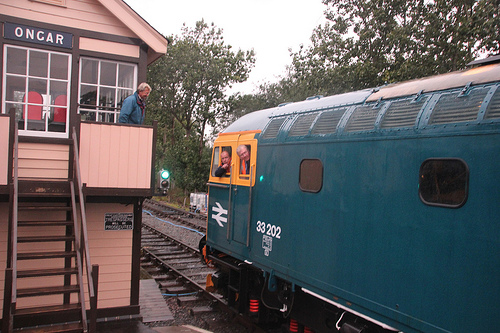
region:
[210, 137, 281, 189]
two person looking out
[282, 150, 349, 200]
a closed windows on side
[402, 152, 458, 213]
a open window in train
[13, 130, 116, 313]
entrance to the house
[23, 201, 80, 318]
steps to enter house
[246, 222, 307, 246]
number of the train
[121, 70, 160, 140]
a person standing in home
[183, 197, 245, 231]
a white symbol on train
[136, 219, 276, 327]
a big rail way track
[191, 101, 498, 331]
last part of the train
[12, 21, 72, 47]
"Ongar" sign on building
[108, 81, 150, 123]
man standing on balcony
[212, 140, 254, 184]
two men looking out train windows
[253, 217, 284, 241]
"33 202" on side of train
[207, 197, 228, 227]
company logo on side of train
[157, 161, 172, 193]
traffic light lit to "green"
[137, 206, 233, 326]
train tracks beside train stop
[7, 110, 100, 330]
stairs leading to second floor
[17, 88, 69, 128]
red-backed chairs on second floor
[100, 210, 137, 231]
black and white sign on first floor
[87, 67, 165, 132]
man standing on a balcony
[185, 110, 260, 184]
people looking out of train windows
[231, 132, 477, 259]
windows on the side of a train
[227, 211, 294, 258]
white numbers on the side of the train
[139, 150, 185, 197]
a green traffic light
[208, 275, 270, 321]
orange springs on the bottom of train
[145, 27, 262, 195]
trees ahead of the train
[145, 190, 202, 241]
a blue chord near tracks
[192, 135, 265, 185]
the conductor in the window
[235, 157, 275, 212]
green light reflected on the train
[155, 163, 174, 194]
green light is lit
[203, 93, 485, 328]
yellow and teal train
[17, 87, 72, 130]
red seats inside waiting area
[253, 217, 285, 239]
33202 labeled on train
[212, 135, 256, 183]
two men looking out of train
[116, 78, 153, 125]
one man standing on platform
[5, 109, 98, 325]
wooden staircase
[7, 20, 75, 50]
sign on platform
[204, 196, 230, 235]
white arrows on train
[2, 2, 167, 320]
tan and brown waiting structure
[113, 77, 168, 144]
The man stands on the balcony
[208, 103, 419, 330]
Train is blue and orange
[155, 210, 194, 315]
The track is sort of rusty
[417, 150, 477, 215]
The side of the train has a window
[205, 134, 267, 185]
Two people look out the window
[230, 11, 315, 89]
The sky is cloudy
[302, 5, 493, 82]
There are many trees around the track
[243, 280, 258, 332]
There are shocks under the train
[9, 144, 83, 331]
Wooden stairs going upstairs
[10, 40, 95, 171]
The window is large